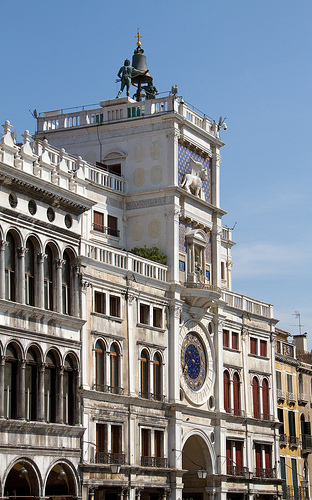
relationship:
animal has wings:
[181, 158, 211, 194] [190, 159, 204, 172]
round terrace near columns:
[178, 318, 215, 407] [167, 307, 181, 403]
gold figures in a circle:
[193, 336, 201, 343] [182, 334, 208, 390]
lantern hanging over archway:
[198, 467, 207, 480] [178, 419, 222, 455]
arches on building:
[3, 453, 81, 494] [3, 112, 303, 491]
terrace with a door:
[182, 225, 215, 288] [195, 244, 207, 278]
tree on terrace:
[130, 246, 165, 261] [182, 225, 215, 288]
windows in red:
[223, 330, 277, 477] [233, 334, 237, 348]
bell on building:
[132, 49, 148, 77] [3, 112, 303, 491]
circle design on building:
[182, 334, 208, 390] [3, 112, 303, 491]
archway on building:
[178, 419, 222, 455] [3, 112, 303, 491]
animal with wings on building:
[181, 158, 211, 194] [3, 112, 303, 491]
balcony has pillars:
[96, 383, 126, 394] [104, 347, 116, 389]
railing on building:
[141, 453, 174, 466] [3, 112, 303, 491]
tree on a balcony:
[130, 246, 165, 261] [96, 383, 126, 394]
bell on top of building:
[132, 49, 148, 77] [3, 112, 303, 491]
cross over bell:
[134, 30, 145, 46] [132, 49, 148, 77]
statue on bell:
[118, 60, 135, 96] [132, 49, 148, 77]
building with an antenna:
[3, 112, 303, 491] [293, 314, 305, 336]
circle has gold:
[182, 334, 208, 390] [193, 336, 201, 343]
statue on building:
[118, 60, 135, 96] [3, 112, 303, 491]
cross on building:
[134, 30, 145, 46] [3, 112, 303, 491]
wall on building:
[125, 130, 172, 186] [3, 112, 303, 491]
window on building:
[96, 294, 106, 315] [3, 112, 303, 491]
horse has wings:
[181, 158, 211, 194] [190, 159, 204, 172]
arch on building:
[182, 430, 217, 457] [3, 112, 303, 491]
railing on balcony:
[141, 453, 174, 466] [96, 383, 126, 394]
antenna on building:
[293, 314, 305, 336] [3, 112, 303, 491]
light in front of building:
[110, 463, 122, 474] [3, 112, 303, 491]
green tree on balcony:
[145, 250, 157, 258] [96, 383, 126, 394]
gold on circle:
[193, 336, 201, 343] [182, 334, 208, 390]